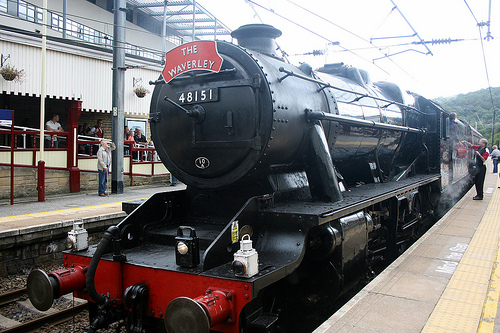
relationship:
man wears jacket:
[80, 143, 126, 201] [92, 146, 111, 166]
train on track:
[69, 75, 497, 313] [5, 269, 87, 331]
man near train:
[451, 130, 489, 214] [69, 75, 497, 313]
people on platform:
[27, 108, 167, 160] [1, 3, 166, 219]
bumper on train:
[37, 264, 192, 330] [69, 75, 497, 313]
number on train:
[168, 75, 222, 114] [69, 75, 497, 313]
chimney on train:
[225, 20, 287, 61] [69, 75, 497, 313]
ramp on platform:
[7, 123, 160, 185] [1, 3, 166, 219]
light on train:
[165, 237, 196, 267] [69, 75, 497, 313]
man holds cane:
[80, 143, 126, 201] [98, 176, 116, 198]